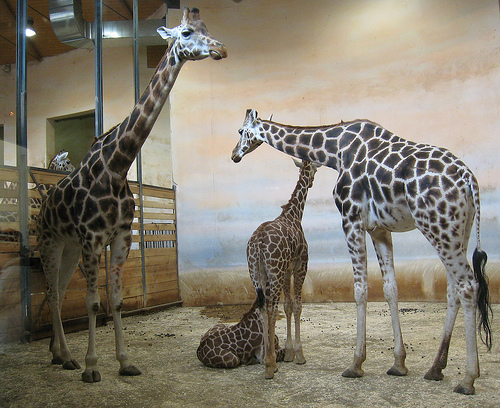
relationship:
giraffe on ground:
[196, 286, 290, 368] [1, 299, 497, 403]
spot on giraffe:
[61, 186, 81, 198] [42, 8, 217, 379]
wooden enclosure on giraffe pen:
[1, 166, 180, 343] [0, 0, 500, 404]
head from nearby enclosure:
[166, 12, 226, 61] [1, 165, 178, 327]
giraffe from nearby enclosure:
[35, 7, 227, 383] [1, 165, 178, 327]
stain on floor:
[191, 295, 298, 334] [166, 303, 496, 387]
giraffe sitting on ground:
[192, 276, 280, 363] [1, 299, 497, 403]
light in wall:
[81, 17, 139, 61] [0, 0, 500, 306]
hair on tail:
[467, 251, 497, 308] [462, 190, 497, 281]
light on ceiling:
[23, 26, 39, 39] [0, 1, 180, 77]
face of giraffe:
[231, 118, 265, 162] [224, 107, 496, 392]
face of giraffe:
[175, 24, 227, 63] [35, 7, 227, 383]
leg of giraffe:
[345, 231, 371, 381] [224, 107, 496, 392]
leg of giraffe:
[368, 231, 409, 376] [224, 107, 496, 392]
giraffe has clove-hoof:
[42, 8, 217, 379] [81, 370, 102, 383]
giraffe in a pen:
[35, 7, 227, 383] [21, 30, 482, 387]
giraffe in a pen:
[224, 107, 496, 392] [11, 11, 490, 396]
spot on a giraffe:
[393, 150, 418, 184] [224, 107, 496, 392]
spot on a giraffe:
[333, 129, 360, 151] [224, 107, 496, 392]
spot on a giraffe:
[310, 129, 326, 149] [224, 107, 496, 392]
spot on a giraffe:
[78, 195, 100, 223] [35, 7, 227, 383]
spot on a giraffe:
[99, 135, 116, 168] [35, 7, 227, 383]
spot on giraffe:
[125, 109, 149, 132] [42, 8, 217, 379]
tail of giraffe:
[469, 172, 494, 352] [224, 107, 496, 392]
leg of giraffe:
[418, 217, 498, 399] [224, 107, 496, 392]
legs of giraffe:
[324, 219, 426, 390] [224, 107, 496, 392]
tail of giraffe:
[250, 242, 280, 300] [247, 157, 323, 379]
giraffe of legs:
[239, 149, 322, 381] [278, 268, 311, 367]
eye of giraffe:
[236, 126, 244, 135] [35, 7, 227, 383]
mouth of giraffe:
[228, 135, 253, 163] [224, 107, 496, 392]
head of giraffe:
[231, 107, 261, 164] [35, 7, 227, 383]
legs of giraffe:
[71, 233, 150, 394] [224, 107, 496, 392]